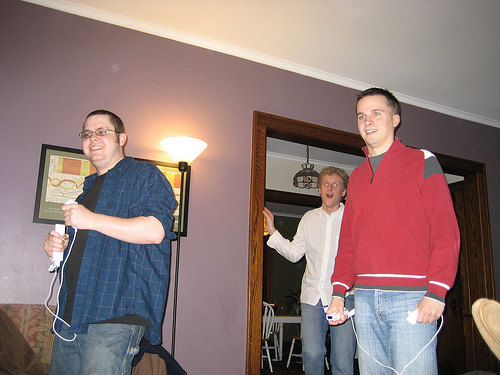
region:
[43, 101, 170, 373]
I guy standing and holding a wii controller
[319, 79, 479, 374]
a guy in a red sweater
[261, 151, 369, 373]
a curlie headed man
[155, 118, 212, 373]
a long lamp that is turned on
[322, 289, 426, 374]
a white wii controller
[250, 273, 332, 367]
a dinning table and chairs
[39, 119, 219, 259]
a picture on a wall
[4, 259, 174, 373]
a comfy looking sofa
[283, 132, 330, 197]
a hanging lamp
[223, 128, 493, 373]
a brown wooden archway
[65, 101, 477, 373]
people are holding white controllers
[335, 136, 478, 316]
man on right is wearing red sweater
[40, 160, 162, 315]
man on left is wearing blue shirt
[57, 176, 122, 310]
man on left has black shirt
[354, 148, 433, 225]
man on right has grey shirt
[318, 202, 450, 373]
man on right wears blue pants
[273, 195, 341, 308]
man in background wears white shirt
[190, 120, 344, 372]
brown frame around doorway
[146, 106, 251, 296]
light is on pole behind man on left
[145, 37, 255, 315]
wall is lavender behind people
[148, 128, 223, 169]
A lit white porcelain lampshade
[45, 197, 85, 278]
Hands holding a wii controller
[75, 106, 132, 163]
A man with a smiling face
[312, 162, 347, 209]
A man with a surprised face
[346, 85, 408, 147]
A man with a stunned face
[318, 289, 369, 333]
A hand holding onto a wii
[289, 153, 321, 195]
A tiffany chandelier on the ceiling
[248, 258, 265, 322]
A wooden door frame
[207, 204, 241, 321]
A lavender color wall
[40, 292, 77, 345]
A white wii cord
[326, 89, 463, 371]
A young playing a game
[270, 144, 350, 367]
a young man in the door way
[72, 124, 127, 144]
Young man glasses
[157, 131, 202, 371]
a light by the wall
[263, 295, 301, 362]
table and chairs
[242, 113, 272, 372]
s door frame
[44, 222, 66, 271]
a controller in right hand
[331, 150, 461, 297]
a red shirt with strips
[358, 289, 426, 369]
boys blue jeans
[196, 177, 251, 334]
a plum wall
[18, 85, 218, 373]
the man holding a remote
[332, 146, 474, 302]
the mans is wearing a red shirt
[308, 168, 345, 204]
the mans face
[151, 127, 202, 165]
the top of the lamp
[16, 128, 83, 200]
part of the picture on the wall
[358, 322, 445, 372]
blue jeans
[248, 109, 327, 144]
wood trim on the door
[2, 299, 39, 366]
part of the couch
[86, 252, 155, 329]
a blue and grey shirt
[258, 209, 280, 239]
a mans hand